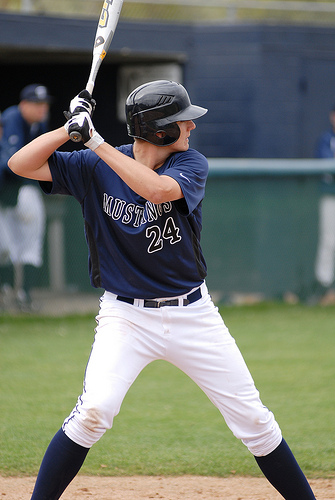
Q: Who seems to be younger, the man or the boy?
A: The boy is younger than the man.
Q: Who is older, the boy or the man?
A: The man is older than the boy.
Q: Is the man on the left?
A: Yes, the man is on the left of the image.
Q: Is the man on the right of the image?
A: No, the man is on the left of the image.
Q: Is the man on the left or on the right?
A: The man is on the left of the image.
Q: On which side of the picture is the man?
A: The man is on the left of the image.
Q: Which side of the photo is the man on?
A: The man is on the left of the image.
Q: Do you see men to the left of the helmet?
A: Yes, there is a man to the left of the helmet.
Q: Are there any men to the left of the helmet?
A: Yes, there is a man to the left of the helmet.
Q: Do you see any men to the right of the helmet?
A: No, the man is to the left of the helmet.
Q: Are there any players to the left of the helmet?
A: No, there is a man to the left of the helmet.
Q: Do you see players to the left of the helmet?
A: No, there is a man to the left of the helmet.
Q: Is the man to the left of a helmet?
A: Yes, the man is to the left of a helmet.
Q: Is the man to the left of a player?
A: No, the man is to the left of a helmet.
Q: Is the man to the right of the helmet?
A: No, the man is to the left of the helmet.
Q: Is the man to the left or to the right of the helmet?
A: The man is to the left of the helmet.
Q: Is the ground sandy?
A: Yes, the ground is sandy.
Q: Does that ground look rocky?
A: No, the ground is sandy.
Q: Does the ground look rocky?
A: No, the ground is sandy.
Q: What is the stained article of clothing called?
A: The clothing item is a uniform.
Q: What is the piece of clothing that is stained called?
A: The clothing item is a uniform.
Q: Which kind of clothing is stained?
A: The clothing is a uniform.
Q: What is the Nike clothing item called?
A: The clothing item is a uniform.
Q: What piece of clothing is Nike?
A: The clothing item is a uniform.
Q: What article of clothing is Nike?
A: The clothing item is a uniform.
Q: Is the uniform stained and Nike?
A: Yes, the uniform is stained and nike.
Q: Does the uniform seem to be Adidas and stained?
A: No, the uniform is stained but nike.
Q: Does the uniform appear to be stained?
A: Yes, the uniform is stained.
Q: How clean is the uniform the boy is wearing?
A: The uniform is stained.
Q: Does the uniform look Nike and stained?
A: Yes, the uniform is Nike and stained.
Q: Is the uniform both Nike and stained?
A: Yes, the uniform is Nike and stained.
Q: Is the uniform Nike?
A: Yes, the uniform is nike.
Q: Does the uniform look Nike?
A: Yes, the uniform is nike.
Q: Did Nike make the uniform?
A: Yes, the uniform was made by nike.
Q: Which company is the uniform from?
A: The uniform is from nike.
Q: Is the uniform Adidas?
A: No, the uniform is nike.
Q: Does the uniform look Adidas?
A: No, the uniform is nike.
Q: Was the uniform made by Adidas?
A: No, the uniform was made by nike.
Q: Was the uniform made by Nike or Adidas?
A: The uniform was made nike.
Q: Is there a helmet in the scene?
A: Yes, there is a helmet.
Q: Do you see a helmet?
A: Yes, there is a helmet.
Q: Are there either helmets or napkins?
A: Yes, there is a helmet.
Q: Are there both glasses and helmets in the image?
A: No, there is a helmet but no glasses.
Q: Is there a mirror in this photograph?
A: No, there are no mirrors.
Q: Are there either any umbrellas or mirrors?
A: No, there are no mirrors or umbrellas.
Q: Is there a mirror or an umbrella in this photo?
A: No, there are no mirrors or umbrellas.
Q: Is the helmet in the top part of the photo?
A: Yes, the helmet is in the top of the image.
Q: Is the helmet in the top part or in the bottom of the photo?
A: The helmet is in the top of the image.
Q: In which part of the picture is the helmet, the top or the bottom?
A: The helmet is in the top of the image.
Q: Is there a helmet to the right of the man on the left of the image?
A: Yes, there is a helmet to the right of the man.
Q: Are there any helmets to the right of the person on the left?
A: Yes, there is a helmet to the right of the man.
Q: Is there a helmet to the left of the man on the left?
A: No, the helmet is to the right of the man.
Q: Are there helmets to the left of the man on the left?
A: No, the helmet is to the right of the man.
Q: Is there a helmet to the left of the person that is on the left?
A: No, the helmet is to the right of the man.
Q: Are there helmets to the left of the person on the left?
A: No, the helmet is to the right of the man.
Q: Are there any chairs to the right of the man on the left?
A: No, there is a helmet to the right of the man.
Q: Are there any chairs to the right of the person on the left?
A: No, there is a helmet to the right of the man.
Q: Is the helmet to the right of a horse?
A: No, the helmet is to the right of the man.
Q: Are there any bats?
A: Yes, there is a bat.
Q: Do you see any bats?
A: Yes, there is a bat.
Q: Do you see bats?
A: Yes, there is a bat.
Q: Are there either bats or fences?
A: Yes, there is a bat.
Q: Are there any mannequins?
A: No, there are no mannequins.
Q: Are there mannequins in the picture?
A: No, there are no mannequins.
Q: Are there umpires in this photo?
A: No, there are no umpires.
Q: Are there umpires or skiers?
A: No, there are no umpires or skiers.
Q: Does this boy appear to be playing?
A: Yes, the boy is playing.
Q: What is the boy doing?
A: The boy is playing.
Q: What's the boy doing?
A: The boy is playing.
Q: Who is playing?
A: The boy is playing.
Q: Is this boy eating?
A: No, the boy is playing.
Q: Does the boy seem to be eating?
A: No, the boy is playing.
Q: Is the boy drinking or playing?
A: The boy is playing.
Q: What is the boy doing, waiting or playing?
A: The boy is playing.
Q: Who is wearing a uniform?
A: The boy is wearing a uniform.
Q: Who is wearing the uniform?
A: The boy is wearing a uniform.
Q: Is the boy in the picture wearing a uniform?
A: Yes, the boy is wearing a uniform.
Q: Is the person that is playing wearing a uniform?
A: Yes, the boy is wearing a uniform.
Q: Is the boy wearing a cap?
A: No, the boy is wearing a uniform.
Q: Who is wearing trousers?
A: The boy is wearing trousers.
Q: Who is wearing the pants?
A: The boy is wearing trousers.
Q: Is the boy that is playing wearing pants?
A: Yes, the boy is wearing pants.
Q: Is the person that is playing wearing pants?
A: Yes, the boy is wearing pants.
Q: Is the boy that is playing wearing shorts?
A: No, the boy is wearing pants.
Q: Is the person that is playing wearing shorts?
A: No, the boy is wearing pants.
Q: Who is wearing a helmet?
A: The boy is wearing a helmet.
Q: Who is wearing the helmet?
A: The boy is wearing a helmet.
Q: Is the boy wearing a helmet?
A: Yes, the boy is wearing a helmet.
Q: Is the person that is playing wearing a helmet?
A: Yes, the boy is wearing a helmet.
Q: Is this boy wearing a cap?
A: No, the boy is wearing a helmet.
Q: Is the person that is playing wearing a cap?
A: No, the boy is wearing a helmet.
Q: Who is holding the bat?
A: The boy is holding the bat.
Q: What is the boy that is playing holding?
A: The boy is holding the bat.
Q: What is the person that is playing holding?
A: The boy is holding the bat.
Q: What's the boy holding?
A: The boy is holding the bat.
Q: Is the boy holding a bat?
A: Yes, the boy is holding a bat.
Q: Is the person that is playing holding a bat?
A: Yes, the boy is holding a bat.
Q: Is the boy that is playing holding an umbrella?
A: No, the boy is holding a bat.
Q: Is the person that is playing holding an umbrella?
A: No, the boy is holding a bat.